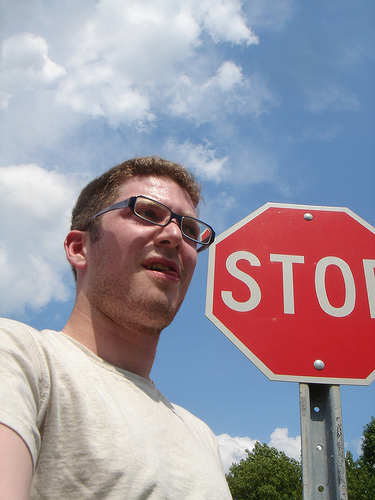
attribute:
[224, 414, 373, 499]
trees — green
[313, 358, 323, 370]
bolt — silver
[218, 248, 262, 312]
letter — white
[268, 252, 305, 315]
letter — white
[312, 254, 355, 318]
letter — white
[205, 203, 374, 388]
sign — red, white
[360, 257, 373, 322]
letter — white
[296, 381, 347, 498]
metal post — large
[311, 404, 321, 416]
hole — small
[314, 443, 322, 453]
hole — small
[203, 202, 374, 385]
stop sign — red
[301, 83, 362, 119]
cloud — white, small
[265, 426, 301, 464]
cloud — white, small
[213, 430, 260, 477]
cloud — small, white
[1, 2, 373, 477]
sky — blue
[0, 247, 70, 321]
cloud — small, white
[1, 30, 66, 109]
cloud — white, small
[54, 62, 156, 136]
cloud — white, small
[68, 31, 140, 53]
cloud — small, white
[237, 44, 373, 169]
sky — blue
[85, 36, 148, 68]
cloud — white, small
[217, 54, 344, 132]
sky — blue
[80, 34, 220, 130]
clouds — white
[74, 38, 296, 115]
sky — blue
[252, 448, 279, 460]
leaves — green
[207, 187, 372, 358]
sign — stop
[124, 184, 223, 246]
glasses — man's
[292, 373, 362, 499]
pole — metal 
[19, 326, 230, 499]
shirt — white, tee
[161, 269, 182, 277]
tongue — sticking out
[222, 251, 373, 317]
letters — white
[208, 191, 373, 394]
sign — red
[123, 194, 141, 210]
frame — black